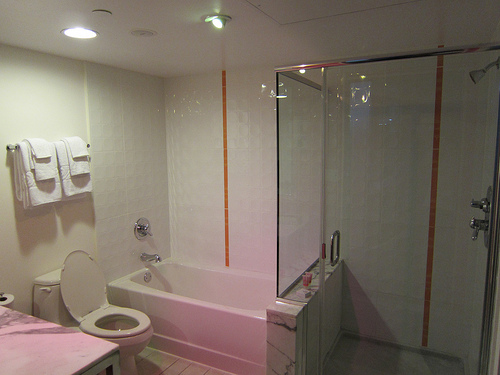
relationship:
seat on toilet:
[84, 301, 148, 337] [59, 251, 151, 371]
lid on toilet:
[59, 247, 110, 320] [33, 251, 155, 375]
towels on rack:
[12, 135, 92, 209] [7, 126, 78, 169]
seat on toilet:
[78, 304, 150, 337] [33, 251, 155, 375]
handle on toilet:
[33, 283, 51, 295] [37, 280, 166, 374]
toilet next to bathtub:
[52, 258, 156, 350] [105, 256, 278, 375]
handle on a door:
[318, 223, 349, 272] [317, 48, 462, 374]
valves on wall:
[468, 186, 498, 253] [477, 20, 495, 373]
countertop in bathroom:
[6, 308, 118, 373] [0, 0, 499, 373]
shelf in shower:
[264, 255, 339, 317] [277, 40, 499, 374]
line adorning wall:
[221, 66, 230, 266] [162, 42, 484, 360]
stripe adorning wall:
[418, 41, 446, 349] [162, 42, 484, 360]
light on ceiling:
[60, 27, 99, 39] [2, 5, 499, 81]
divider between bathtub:
[274, 69, 326, 299] [106, 251, 296, 373]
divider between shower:
[274, 69, 326, 299] [307, 42, 499, 374]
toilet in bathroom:
[33, 251, 155, 375] [0, 52, 453, 371]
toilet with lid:
[33, 251, 155, 375] [59, 245, 111, 314]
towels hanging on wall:
[12, 135, 92, 209] [1, 44, 171, 321]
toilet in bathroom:
[33, 251, 155, 375] [0, 0, 499, 373]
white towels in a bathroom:
[6, 134, 101, 213] [45, 61, 368, 341]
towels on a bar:
[12, 135, 92, 209] [6, 134, 95, 154]